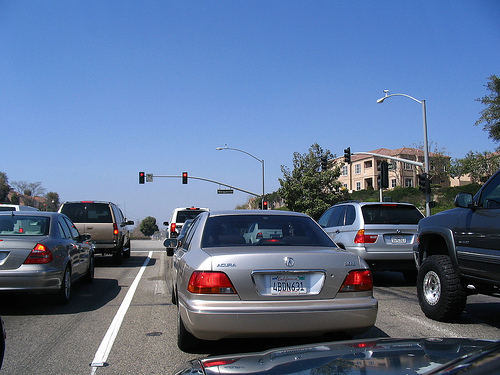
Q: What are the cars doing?
A: Stopped.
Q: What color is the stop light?
A: Red.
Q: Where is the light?
A: Above the street.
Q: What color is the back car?
A: Silver.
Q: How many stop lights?
A: 2.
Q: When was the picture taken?
A: Daytime.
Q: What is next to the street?
A: Trees.